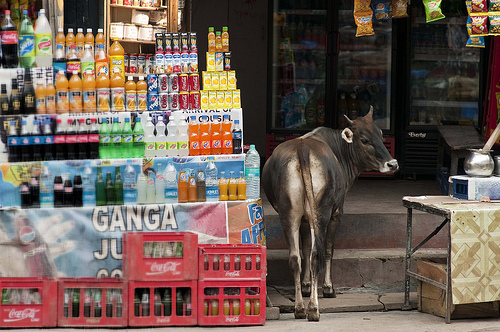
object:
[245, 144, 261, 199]
bottle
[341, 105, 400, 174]
head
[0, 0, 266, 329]
beverages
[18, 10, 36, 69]
drinks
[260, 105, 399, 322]
cow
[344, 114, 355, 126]
horn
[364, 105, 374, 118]
horn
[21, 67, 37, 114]
soda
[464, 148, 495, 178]
pot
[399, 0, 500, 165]
cooler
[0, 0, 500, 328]
building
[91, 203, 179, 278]
sign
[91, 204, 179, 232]
lettering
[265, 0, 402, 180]
refrigerator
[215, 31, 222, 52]
soda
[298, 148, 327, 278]
tail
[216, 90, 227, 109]
soda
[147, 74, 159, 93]
soda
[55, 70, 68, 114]
soda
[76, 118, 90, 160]
soda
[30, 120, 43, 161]
soda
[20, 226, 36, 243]
logo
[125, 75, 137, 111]
drinks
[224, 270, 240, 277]
logo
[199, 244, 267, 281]
bin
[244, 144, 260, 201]
drink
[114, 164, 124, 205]
drink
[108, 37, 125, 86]
drink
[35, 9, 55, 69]
drink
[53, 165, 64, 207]
drink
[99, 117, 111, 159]
soda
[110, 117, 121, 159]
soda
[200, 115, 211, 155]
soda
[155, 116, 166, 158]
soda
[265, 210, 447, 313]
stairs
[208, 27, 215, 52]
bottle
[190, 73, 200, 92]
drinks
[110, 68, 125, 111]
drinks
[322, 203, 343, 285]
leg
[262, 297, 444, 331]
sidewalk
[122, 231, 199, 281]
bins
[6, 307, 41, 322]
sign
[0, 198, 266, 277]
table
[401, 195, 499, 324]
table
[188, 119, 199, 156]
liquid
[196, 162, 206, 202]
drinks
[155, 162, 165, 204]
drinks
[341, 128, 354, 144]
ear